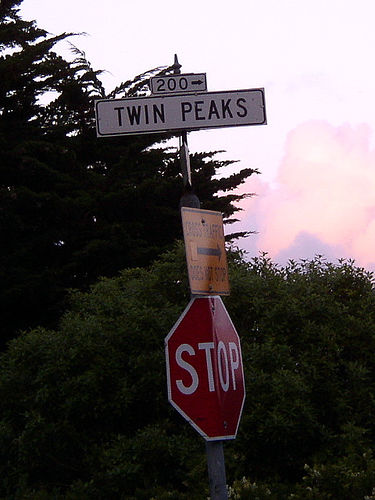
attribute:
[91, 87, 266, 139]
longer sign — long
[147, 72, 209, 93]
street sign — small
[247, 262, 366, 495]
bush — big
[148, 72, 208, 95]
street sign — square, rectangle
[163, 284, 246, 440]
stop sign — red with white trim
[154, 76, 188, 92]
number — black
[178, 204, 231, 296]
sign — square, orange, yellow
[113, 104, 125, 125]
letter — black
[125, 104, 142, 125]
letter — black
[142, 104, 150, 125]
letter — black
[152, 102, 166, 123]
letter — black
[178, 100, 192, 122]
letter — black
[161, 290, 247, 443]
sign — red and white  , red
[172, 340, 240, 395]
writing — white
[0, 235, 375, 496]
foilage — green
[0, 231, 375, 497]
bushes — lush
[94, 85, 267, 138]
sign — rectangle, white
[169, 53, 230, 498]
pole — gray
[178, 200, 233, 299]
sign — black , orange 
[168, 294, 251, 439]
sign — pair 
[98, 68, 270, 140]
sign —  white and black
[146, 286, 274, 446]
sign —  red stop 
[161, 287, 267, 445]
sign — Directional , stop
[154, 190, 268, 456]
sign — street, other 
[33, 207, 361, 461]
trees — two separate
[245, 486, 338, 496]
street —  200 black 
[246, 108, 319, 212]
clouds — fluffy 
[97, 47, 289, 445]
signs — Many , single 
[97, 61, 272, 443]
sign — stop , bottom 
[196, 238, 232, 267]
arrow — black 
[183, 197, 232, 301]
sign — orange 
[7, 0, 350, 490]
night — setting 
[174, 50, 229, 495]
pole — metal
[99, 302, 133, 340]
leaves — green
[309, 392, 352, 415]
leaves — green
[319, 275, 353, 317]
leaves — green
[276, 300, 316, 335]
leaves — green